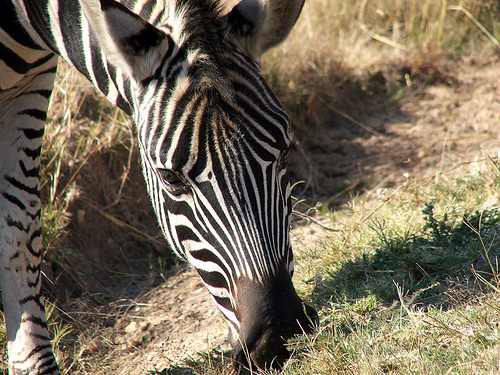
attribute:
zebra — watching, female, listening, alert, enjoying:
[3, 1, 320, 374]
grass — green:
[161, 169, 499, 374]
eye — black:
[156, 167, 182, 191]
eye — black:
[280, 140, 293, 164]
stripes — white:
[202, 196, 225, 240]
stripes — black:
[153, 108, 195, 144]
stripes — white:
[243, 84, 269, 126]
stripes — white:
[31, 6, 79, 35]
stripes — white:
[5, 173, 40, 213]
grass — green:
[0, 313, 230, 374]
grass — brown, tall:
[294, 1, 498, 80]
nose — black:
[235, 309, 320, 370]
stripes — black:
[62, 25, 83, 44]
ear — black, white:
[102, 2, 173, 80]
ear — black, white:
[233, 3, 304, 52]